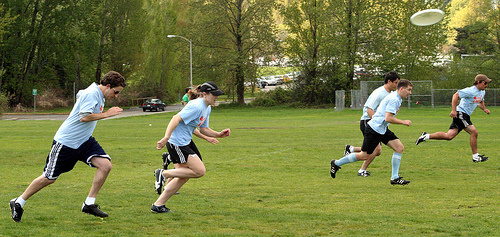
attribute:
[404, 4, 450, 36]
frisbee — white, game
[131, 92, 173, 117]
car — moving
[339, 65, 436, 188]
man — wearing, running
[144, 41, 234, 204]
woman — wearnig, wearing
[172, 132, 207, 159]
short — black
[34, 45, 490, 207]
people — running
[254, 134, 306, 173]
grass — green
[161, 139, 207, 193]
pant — black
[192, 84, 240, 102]
cap — black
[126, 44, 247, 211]
female — a girl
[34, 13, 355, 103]
tree — background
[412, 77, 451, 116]
fence — behind players, silver, chain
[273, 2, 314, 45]
sky — sunny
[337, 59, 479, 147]
men — running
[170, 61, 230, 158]
girl — running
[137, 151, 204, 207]
foot — raised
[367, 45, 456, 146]
athlete — running, wearing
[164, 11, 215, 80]
light — street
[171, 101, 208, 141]
shirt — t